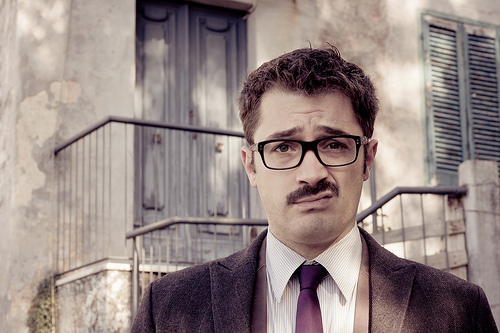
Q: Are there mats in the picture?
A: No, there are no mats.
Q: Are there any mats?
A: No, there are no mats.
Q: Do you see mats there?
A: No, there are no mats.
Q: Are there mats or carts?
A: No, there are no mats or carts.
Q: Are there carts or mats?
A: No, there are no mats or carts.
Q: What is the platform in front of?
A: The platform is in front of the door.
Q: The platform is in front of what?
A: The platform is in front of the door.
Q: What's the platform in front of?
A: The platform is in front of the door.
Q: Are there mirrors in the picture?
A: No, there are no mirrors.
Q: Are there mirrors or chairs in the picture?
A: No, there are no mirrors or chairs.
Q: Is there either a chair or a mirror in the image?
A: No, there are no mirrors or chairs.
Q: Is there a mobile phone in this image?
A: No, there are no cell phones.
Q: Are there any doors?
A: Yes, there is a door.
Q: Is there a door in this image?
A: Yes, there is a door.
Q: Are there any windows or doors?
A: Yes, there is a door.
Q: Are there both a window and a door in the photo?
A: Yes, there are both a door and a window.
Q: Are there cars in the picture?
A: No, there are no cars.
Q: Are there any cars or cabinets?
A: No, there are no cars or cabinets.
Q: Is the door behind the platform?
A: Yes, the door is behind the platform.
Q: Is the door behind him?
A: Yes, the door is behind the man.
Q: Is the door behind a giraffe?
A: No, the door is behind the man.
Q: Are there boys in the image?
A: No, there are no boys.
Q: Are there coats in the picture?
A: Yes, there is a coat.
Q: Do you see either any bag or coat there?
A: Yes, there is a coat.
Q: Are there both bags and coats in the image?
A: No, there is a coat but no bags.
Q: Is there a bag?
A: No, there are no bags.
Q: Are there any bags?
A: No, there are no bags.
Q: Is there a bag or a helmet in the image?
A: No, there are no bags or helmets.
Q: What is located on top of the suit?
A: The coat is on top of the suit.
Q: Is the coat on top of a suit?
A: Yes, the coat is on top of a suit.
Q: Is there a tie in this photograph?
A: Yes, there is a tie.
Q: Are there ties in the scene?
A: Yes, there is a tie.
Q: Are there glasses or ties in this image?
A: Yes, there is a tie.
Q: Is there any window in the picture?
A: Yes, there is a window.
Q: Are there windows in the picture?
A: Yes, there is a window.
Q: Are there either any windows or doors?
A: Yes, there is a window.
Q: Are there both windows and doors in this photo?
A: Yes, there are both a window and a door.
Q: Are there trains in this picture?
A: No, there are no trains.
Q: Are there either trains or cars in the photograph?
A: No, there are no trains or cars.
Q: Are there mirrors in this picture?
A: No, there are no mirrors.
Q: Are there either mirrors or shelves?
A: No, there are no mirrors or shelves.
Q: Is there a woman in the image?
A: No, there are no women.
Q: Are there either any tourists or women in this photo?
A: No, there are no women or tourists.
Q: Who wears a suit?
A: The man wears a suit.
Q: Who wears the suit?
A: The man wears a suit.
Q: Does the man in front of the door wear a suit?
A: Yes, the man wears a suit.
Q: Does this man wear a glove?
A: No, the man wears a suit.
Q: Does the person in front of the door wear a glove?
A: No, the man wears a suit.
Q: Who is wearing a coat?
A: The man is wearing a coat.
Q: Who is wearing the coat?
A: The man is wearing a coat.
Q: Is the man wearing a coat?
A: Yes, the man is wearing a coat.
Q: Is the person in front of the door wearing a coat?
A: Yes, the man is wearing a coat.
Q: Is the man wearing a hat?
A: No, the man is wearing a coat.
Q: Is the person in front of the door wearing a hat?
A: No, the man is wearing a coat.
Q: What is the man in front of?
A: The man is in front of the door.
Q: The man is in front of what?
A: The man is in front of the door.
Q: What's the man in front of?
A: The man is in front of the door.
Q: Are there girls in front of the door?
A: No, there is a man in front of the door.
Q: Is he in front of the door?
A: Yes, the man is in front of the door.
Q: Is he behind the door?
A: No, the man is in front of the door.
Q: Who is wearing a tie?
A: The man is wearing a tie.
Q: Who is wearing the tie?
A: The man is wearing a tie.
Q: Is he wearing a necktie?
A: Yes, the man is wearing a necktie.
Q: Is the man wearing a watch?
A: No, the man is wearing a necktie.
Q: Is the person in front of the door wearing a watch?
A: No, the man is wearing a necktie.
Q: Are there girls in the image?
A: No, there are no girls.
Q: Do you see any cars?
A: No, there are no cars.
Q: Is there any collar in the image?
A: Yes, there is a collar.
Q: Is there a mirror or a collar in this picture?
A: Yes, there is a collar.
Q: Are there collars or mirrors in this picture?
A: Yes, there is a collar.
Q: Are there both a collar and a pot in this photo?
A: No, there is a collar but no pots.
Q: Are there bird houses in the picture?
A: No, there are no bird houses.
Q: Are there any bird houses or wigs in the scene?
A: No, there are no bird houses or wigs.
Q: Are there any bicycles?
A: No, there are no bicycles.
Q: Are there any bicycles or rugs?
A: No, there are no bicycles or rugs.